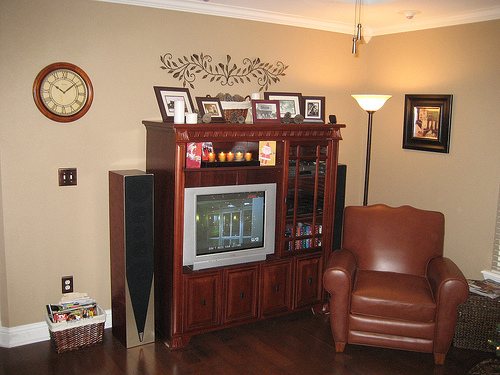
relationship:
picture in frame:
[410, 103, 445, 143] [395, 90, 456, 164]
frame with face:
[28, 60, 93, 124] [42, 70, 86, 113]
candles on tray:
[204, 150, 255, 160] [203, 160, 258, 168]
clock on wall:
[32, 60, 93, 119] [6, 0, 367, 350]